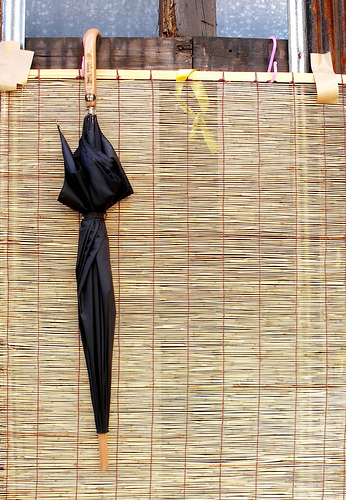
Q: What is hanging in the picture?
A: An umbrella.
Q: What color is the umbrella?
A: Black.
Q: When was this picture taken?
A: Daytime.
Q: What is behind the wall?
A: A window.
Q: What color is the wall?
A: Brown.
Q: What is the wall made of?
A: Wicker.